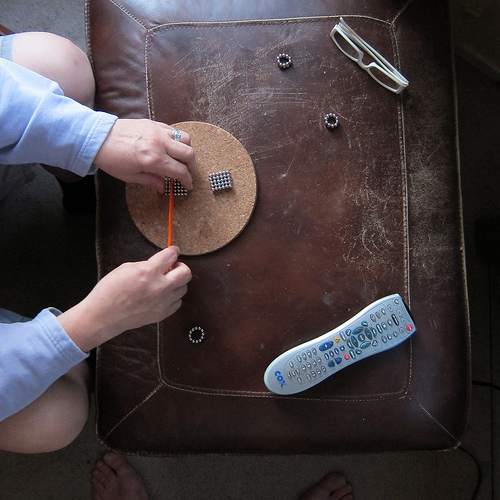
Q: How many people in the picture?
A: Two.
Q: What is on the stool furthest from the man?
A: Glasses.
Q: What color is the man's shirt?
A: Blue.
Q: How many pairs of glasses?
A: One.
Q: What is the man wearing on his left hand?
A: A ring.